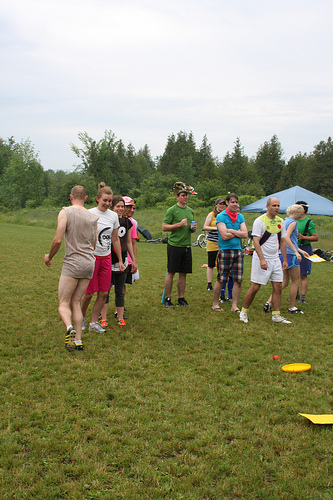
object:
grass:
[1, 216, 331, 500]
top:
[205, 212, 219, 247]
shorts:
[207, 244, 220, 269]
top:
[86, 206, 119, 256]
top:
[163, 203, 199, 244]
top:
[126, 217, 139, 261]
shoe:
[116, 315, 126, 328]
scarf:
[225, 209, 239, 224]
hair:
[111, 195, 126, 208]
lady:
[102, 193, 138, 331]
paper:
[304, 252, 327, 264]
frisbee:
[280, 362, 311, 372]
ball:
[273, 354, 279, 361]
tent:
[239, 183, 333, 217]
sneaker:
[100, 319, 109, 329]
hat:
[172, 180, 198, 197]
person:
[45, 183, 98, 354]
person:
[87, 180, 126, 338]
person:
[160, 180, 198, 310]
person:
[211, 193, 248, 313]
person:
[238, 195, 291, 329]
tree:
[156, 132, 194, 188]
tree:
[68, 127, 118, 195]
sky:
[0, 2, 333, 157]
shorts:
[250, 247, 285, 286]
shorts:
[216, 245, 243, 285]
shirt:
[217, 208, 246, 253]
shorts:
[165, 240, 192, 276]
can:
[190, 220, 195, 229]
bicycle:
[198, 229, 210, 250]